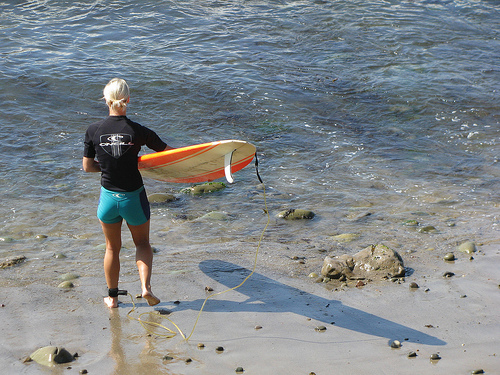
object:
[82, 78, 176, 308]
woman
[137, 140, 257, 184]
surfboard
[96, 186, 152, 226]
shorts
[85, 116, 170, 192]
top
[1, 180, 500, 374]
sand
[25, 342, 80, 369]
rocks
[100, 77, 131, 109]
hair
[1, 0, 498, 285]
water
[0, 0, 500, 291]
ripples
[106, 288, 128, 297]
object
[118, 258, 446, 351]
shadow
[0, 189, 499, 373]
beach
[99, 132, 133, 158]
white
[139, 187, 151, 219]
black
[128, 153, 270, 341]
cord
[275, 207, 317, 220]
rock